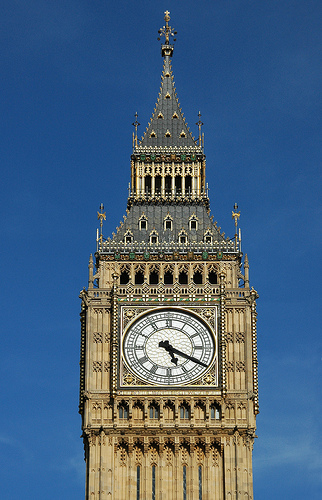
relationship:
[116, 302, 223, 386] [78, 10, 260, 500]
clock on building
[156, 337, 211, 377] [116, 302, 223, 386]
hands on clock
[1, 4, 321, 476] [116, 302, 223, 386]
sky behind clock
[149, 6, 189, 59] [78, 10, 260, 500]
tip of building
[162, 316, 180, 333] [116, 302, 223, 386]
numeral on clock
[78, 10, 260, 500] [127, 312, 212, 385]
building with face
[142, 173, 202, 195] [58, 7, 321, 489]
windows on building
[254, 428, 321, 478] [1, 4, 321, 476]
cloud in sky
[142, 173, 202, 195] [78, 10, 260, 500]
windows on building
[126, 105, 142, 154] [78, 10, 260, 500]
edge of building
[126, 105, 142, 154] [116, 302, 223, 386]
edge of clock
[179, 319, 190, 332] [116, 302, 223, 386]
number on clock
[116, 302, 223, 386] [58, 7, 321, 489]
clock on building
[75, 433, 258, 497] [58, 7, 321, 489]
bottom of building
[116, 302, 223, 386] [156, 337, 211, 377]
clock has hands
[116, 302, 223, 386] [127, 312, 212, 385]
clock has face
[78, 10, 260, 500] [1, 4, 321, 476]
building in sky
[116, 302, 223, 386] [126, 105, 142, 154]
clock has edge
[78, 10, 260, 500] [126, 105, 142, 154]
building on edge